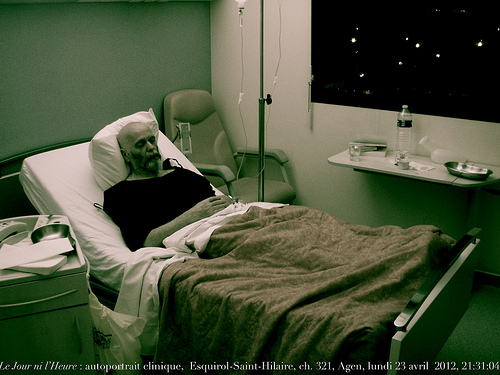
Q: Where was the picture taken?
A: A hospital.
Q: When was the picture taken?
A: Nighttime.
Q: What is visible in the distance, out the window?
A: Lights.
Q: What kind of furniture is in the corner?
A: A chair.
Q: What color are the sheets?
A: White.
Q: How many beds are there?
A: One.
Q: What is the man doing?
A: Sleeping.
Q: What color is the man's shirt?
A: Black.